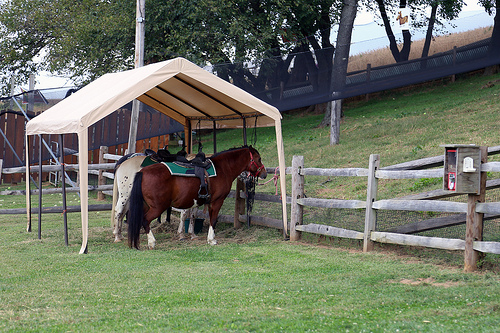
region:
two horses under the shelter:
[110, 134, 258, 253]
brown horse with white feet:
[130, 152, 267, 249]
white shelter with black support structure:
[28, 57, 292, 239]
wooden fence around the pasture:
[8, 141, 493, 265]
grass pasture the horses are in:
[3, 216, 490, 332]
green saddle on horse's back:
[163, 153, 215, 183]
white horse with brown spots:
[101, 154, 152, 251]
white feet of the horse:
[141, 232, 216, 250]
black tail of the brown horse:
[125, 173, 147, 242]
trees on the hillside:
[8, 2, 445, 115]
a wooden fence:
[295, 159, 402, 253]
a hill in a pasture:
[301, 33, 487, 173]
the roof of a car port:
[9, 20, 308, 135]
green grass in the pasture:
[151, 250, 312, 330]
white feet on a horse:
[192, 225, 218, 252]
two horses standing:
[93, 144, 268, 250]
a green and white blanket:
[164, 163, 185, 192]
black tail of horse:
[120, 169, 145, 261]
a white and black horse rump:
[107, 155, 147, 189]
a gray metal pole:
[54, 129, 81, 252]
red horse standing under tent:
[120, 138, 270, 256]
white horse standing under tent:
[108, 148, 234, 248]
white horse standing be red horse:
[106, 144, 277, 255]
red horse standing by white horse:
[103, 137, 272, 254]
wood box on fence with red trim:
[439, 137, 484, 201]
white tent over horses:
[17, 54, 298, 260]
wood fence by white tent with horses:
[235, 149, 311, 234]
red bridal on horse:
[245, 145, 270, 180]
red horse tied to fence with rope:
[122, 137, 298, 252]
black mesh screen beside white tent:
[11, 89, 75, 158]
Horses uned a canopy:
[26, 55, 289, 254]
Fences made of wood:
[1, 144, 498, 269]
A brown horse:
[131, 145, 267, 250]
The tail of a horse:
[126, 170, 144, 247]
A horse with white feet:
[146, 225, 217, 245]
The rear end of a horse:
[116, 150, 148, 187]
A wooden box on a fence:
[440, 140, 482, 197]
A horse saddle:
[170, 150, 215, 198]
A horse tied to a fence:
[129, 143, 281, 250]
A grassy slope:
[183, 56, 498, 244]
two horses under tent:
[121, 129, 249, 233]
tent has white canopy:
[36, 66, 252, 156]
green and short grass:
[96, 278, 236, 318]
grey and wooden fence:
[274, 128, 477, 246]